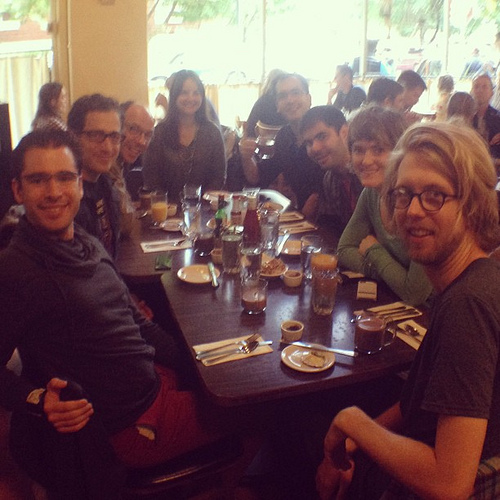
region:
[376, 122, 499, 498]
Man in glasses with blonde hair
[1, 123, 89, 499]
Man in blue shirt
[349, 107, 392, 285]
Woman in green shirt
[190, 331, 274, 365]
Fork and spoon utensil on a piece of napkin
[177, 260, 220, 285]
Small white plate with butter knife placed on top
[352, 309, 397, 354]
A cup of coffee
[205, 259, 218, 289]
Butter knife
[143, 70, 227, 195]
Brunette hair woman wearing grey shirt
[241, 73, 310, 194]
Man holding a drink in his right hand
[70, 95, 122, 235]
A man with eyeglasses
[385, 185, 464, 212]
black rimmed glasses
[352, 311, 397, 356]
glass mug sitting on table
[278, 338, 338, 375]
white round plate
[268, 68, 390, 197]
group of people smiling at camera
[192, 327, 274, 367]
silverware sitting on napkin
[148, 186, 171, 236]
tall glass on table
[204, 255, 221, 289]
butter knife sitting on plate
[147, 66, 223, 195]
woman wearing dark shirt smiling at camera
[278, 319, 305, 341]
small round bowl on table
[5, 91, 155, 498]
group of friends smiling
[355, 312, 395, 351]
a cup of dark brown liquid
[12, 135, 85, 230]
the face of a young man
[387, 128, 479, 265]
the face of a young man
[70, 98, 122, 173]
the face of a young man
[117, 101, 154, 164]
the face of an older man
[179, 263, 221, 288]
a small plate and knife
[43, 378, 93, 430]
the hand of a man on a chair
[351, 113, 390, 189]
the face of a young woman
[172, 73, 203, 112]
the face of a young woman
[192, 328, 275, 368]
a fork spoon and knife on a napkin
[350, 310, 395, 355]
clear glass mug on table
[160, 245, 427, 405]
dark brown wood table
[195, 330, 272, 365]
white rectangle napkin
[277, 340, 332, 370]
round white saucer on table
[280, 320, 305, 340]
small sauce cup on table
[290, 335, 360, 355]
silver butter knife on saucer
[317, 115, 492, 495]
man with long hair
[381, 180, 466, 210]
black glasses on man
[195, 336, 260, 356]
silver spoon on napkin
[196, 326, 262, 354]
fork next to spoon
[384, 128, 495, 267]
the face of a blond man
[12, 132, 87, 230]
the face of a man with glasses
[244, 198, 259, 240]
a glass bottle with red liquid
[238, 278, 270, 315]
glass cup holding brown liquid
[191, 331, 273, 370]
fork and spoon on a napkin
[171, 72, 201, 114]
face of a woman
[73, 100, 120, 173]
the face of a man with glasses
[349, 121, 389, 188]
face of a young woman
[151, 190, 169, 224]
a glass of orange liquid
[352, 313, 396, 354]
a glass holding brown liquid